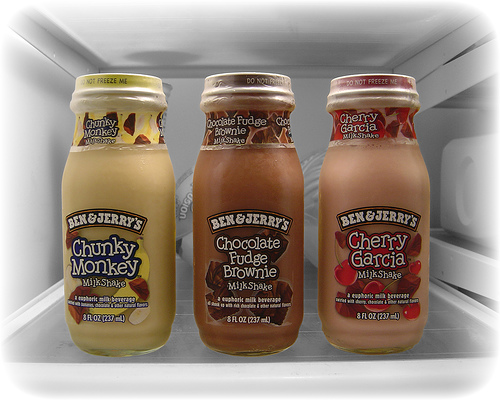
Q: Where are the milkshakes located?
A: In the refrigerator.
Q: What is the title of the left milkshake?
A: Chunky Monkey.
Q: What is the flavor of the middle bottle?
A: Chocolate fudge brownie.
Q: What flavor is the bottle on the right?
A: Cherry garcia.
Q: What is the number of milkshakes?
A: Three.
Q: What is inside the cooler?
A: The jars.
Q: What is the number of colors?
A: Three.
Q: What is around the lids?
A: Seal tape.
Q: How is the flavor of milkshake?
A: Chunky.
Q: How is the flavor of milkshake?
A: Chocolate.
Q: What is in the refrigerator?
A: Milk shake.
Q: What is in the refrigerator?
A: Milkshake.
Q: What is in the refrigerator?
A: Milkshake.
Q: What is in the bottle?
A: Milkshake.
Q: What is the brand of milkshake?
A: Ben & jerrys.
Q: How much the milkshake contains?
A: 237 ml.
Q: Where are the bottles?
A: In fridge.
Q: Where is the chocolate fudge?
A: In middle.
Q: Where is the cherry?
A: On right.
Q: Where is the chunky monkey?
A: On left.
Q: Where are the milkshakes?
A: Glass jars.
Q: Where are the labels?
A: On bottles.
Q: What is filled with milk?
A: The bottles.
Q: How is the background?
A: White.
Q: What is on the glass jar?
A: A label.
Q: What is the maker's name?
A: Ben and jerry's.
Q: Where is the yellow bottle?
A: On the left.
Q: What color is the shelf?
A: White.